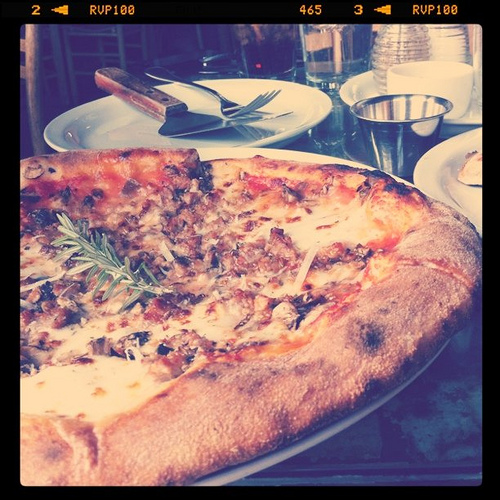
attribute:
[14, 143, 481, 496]
pizza — grilled, large, baked, cooked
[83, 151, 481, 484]
plate — white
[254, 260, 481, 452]
crust — tan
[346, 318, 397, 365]
burn mark — brown, black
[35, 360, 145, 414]
cheese — white, melted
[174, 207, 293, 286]
sausage — brown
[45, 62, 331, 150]
white plate — round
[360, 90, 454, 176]
bowl — metal, small, shiny, empty, silver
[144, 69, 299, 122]
fork — silver, silver tone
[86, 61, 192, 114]
handle — brown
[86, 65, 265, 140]
spatula — metal, wooden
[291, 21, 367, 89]
glass cup — empty, clear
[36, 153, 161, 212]
sauce — red